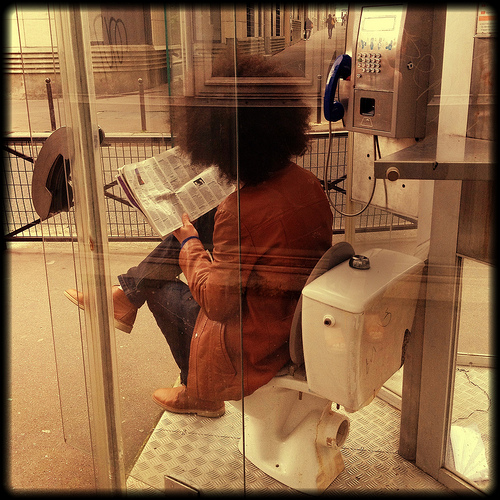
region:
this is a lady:
[113, 62, 284, 354]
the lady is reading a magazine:
[128, 162, 200, 227]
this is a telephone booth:
[319, 11, 408, 138]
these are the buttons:
[356, 50, 379, 72]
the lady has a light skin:
[180, 227, 191, 234]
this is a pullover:
[230, 209, 284, 326]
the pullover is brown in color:
[258, 302, 265, 341]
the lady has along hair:
[229, 115, 276, 157]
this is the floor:
[20, 377, 62, 434]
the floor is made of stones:
[30, 395, 54, 442]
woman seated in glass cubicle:
[57, 31, 470, 423]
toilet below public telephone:
[130, 22, 455, 457]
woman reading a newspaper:
[105, 62, 290, 247]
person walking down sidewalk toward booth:
[85, 10, 385, 122]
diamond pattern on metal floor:
[145, 415, 240, 491]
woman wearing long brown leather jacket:
[170, 145, 340, 405]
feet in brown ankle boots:
[56, 266, 228, 431]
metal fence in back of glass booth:
[10, 106, 410, 261]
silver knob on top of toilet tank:
[342, 240, 374, 286]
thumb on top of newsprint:
[145, 186, 205, 256]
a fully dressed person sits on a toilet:
[68, 45, 426, 487]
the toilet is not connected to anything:
[234, 245, 409, 487]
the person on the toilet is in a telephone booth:
[54, 16, 476, 488]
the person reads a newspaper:
[103, 66, 399, 463]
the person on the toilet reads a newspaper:
[68, 52, 422, 487]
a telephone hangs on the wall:
[317, 12, 434, 171]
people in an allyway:
[236, 10, 361, 121]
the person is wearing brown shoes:
[75, 93, 356, 417]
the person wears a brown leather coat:
[79, 63, 351, 420]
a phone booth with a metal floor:
[59, 12, 499, 497]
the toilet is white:
[291, 267, 410, 477]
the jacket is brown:
[198, 207, 330, 404]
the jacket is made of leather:
[180, 220, 300, 400]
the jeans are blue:
[135, 259, 195, 343]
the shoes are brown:
[151, 387, 228, 419]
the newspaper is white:
[123, 179, 233, 240]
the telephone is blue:
[316, 52, 361, 119]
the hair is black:
[173, 72, 330, 175]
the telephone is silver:
[358, 14, 413, 135]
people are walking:
[301, 14, 347, 40]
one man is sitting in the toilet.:
[134, 62, 336, 406]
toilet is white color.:
[259, 341, 345, 471]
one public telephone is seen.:
[314, 0, 409, 135]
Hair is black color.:
[216, 92, 281, 151]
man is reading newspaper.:
[117, 111, 271, 291]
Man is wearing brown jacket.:
[215, 214, 274, 316]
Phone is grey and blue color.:
[323, 18, 408, 131]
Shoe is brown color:
[76, 277, 214, 419]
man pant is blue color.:
[133, 263, 200, 358]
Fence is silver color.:
[13, 123, 131, 249]